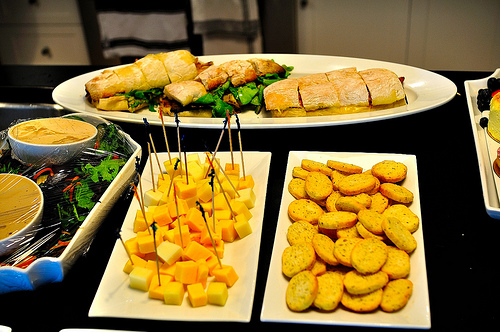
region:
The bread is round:
[284, 266, 316, 308]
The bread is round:
[283, 241, 315, 273]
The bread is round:
[315, 271, 340, 309]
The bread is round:
[348, 236, 391, 273]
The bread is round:
[381, 210, 417, 252]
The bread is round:
[381, 271, 411, 311]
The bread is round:
[287, 196, 323, 223]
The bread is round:
[301, 167, 333, 201]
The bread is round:
[336, 171, 376, 194]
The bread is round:
[366, 152, 408, 187]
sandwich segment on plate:
[364, 65, 404, 110]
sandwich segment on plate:
[333, 67, 366, 114]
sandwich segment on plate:
[294, 72, 338, 112]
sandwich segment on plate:
[262, 75, 303, 115]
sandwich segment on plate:
[255, 56, 277, 81]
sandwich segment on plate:
[231, 62, 252, 103]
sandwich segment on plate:
[197, 62, 227, 107]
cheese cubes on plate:
[155, 154, 239, 305]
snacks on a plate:
[290, 154, 408, 316]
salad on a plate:
[1, 110, 105, 250]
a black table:
[11, 70, 493, 330]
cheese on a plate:
[135, 143, 233, 322]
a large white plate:
[74, 42, 449, 132]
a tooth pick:
[196, 202, 232, 259]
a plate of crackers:
[284, 155, 414, 319]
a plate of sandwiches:
[76, 48, 396, 108]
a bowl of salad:
[0, 127, 107, 289]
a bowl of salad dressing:
[11, 116, 81, 156]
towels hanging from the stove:
[101, 8, 271, 47]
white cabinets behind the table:
[298, 0, 490, 72]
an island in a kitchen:
[6, 5, 496, 330]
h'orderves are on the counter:
[7, 49, 495, 324]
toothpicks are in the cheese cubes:
[121, 144, 257, 316]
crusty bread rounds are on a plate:
[283, 149, 419, 322]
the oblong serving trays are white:
[91, 143, 436, 328]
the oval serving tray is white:
[48, 49, 461, 129]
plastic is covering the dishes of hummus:
[2, 113, 132, 308]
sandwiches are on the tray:
[80, 46, 408, 119]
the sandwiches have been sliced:
[77, 43, 408, 118]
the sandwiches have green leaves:
[118, 67, 289, 108]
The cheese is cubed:
[205, 275, 227, 305]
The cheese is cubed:
[186, 280, 206, 307]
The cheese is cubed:
[161, 275, 183, 306]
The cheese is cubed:
[147, 270, 169, 298]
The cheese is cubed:
[125, 263, 152, 293]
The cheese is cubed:
[210, 257, 238, 286]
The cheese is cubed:
[172, 254, 198, 286]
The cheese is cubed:
[176, 240, 211, 262]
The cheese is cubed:
[154, 235, 183, 264]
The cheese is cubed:
[134, 224, 161, 252]